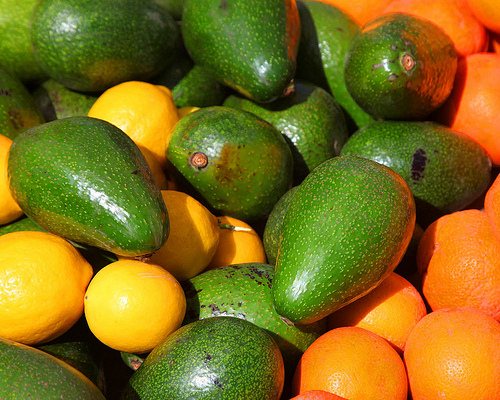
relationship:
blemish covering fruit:
[412, 145, 427, 183] [338, 111, 498, 230]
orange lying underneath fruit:
[296, 325, 407, 398] [269, 151, 419, 329]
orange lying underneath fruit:
[328, 268, 428, 355] [269, 151, 419, 329]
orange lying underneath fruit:
[403, 302, 483, 396] [269, 151, 419, 329]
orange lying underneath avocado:
[413, 207, 483, 313] [340, 122, 494, 215]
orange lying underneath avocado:
[436, 48, 484, 161] [340, 122, 494, 215]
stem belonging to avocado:
[191, 152, 207, 167] [163, 106, 294, 217]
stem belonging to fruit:
[394, 44, 418, 74] [342, 10, 462, 120]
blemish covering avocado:
[410, 148, 428, 185] [340, 110, 498, 207]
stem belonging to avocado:
[190, 150, 212, 175] [163, 101, 300, 226]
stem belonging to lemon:
[218, 216, 255, 238] [115, 188, 223, 281]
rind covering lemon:
[82, 258, 188, 350] [78, 255, 190, 357]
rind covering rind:
[83, 260, 187, 354] [82, 258, 188, 350]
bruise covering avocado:
[183, 144, 244, 184] [163, 101, 300, 226]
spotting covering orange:
[436, 319, 451, 340] [405, 306, 492, 370]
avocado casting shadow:
[177, 1, 303, 107] [292, 3, 348, 103]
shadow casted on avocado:
[292, 3, 348, 103] [296, 1, 376, 125]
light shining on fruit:
[61, 166, 137, 228] [7, 113, 171, 258]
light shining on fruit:
[288, 245, 323, 308] [269, 151, 419, 329]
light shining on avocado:
[193, 132, 228, 157] [163, 106, 294, 217]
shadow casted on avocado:
[405, 188, 444, 226] [340, 122, 494, 215]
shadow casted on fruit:
[179, 271, 201, 328] [181, 260, 328, 371]